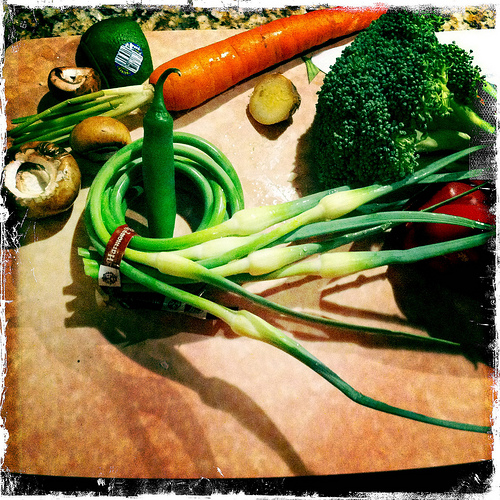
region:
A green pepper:
[141, 72, 201, 241]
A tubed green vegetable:
[79, 137, 489, 389]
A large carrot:
[155, 1, 402, 118]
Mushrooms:
[8, 117, 132, 248]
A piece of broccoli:
[306, 22, 498, 196]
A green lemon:
[71, 20, 163, 99]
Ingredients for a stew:
[14, 22, 499, 452]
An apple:
[372, 158, 499, 318]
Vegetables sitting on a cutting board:
[13, 28, 495, 465]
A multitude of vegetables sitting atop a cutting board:
[15, 21, 499, 453]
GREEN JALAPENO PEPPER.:
[113, 47, 193, 236]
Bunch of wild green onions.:
[128, 147, 455, 454]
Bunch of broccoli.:
[293, 23, 462, 208]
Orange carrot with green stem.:
[8, 0, 389, 116]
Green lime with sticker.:
[82, 19, 160, 104]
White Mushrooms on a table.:
[0, 110, 131, 225]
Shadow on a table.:
[36, 339, 361, 490]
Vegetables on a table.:
[0, 12, 481, 491]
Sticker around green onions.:
[68, 219, 148, 344]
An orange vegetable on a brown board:
[21, 26, 384, 104]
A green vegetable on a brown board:
[73, 218, 372, 383]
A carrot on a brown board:
[76, 17, 386, 84]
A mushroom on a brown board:
[16, 107, 100, 251]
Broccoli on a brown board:
[308, 44, 468, 215]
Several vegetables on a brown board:
[23, 57, 438, 311]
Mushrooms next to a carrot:
[20, 53, 137, 181]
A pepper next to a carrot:
[97, 49, 194, 207]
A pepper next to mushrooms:
[18, 123, 179, 231]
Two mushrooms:
[5, 130, 130, 227]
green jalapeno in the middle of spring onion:
[132, 47, 214, 251]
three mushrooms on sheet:
[10, 56, 124, 221]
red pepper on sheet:
[412, 177, 499, 260]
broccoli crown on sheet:
[305, 0, 498, 200]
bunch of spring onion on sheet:
[66, 111, 488, 436]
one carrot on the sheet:
[20, 0, 443, 155]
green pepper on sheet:
[61, 0, 167, 107]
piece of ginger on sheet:
[237, 58, 313, 154]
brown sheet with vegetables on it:
[10, 2, 499, 499]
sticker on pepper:
[112, 26, 157, 89]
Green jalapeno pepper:
[143, 66, 180, 238]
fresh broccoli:
[336, 17, 478, 167]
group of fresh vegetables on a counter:
[11, 16, 493, 396]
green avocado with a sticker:
[85, 22, 152, 82]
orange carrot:
[172, 14, 342, 69]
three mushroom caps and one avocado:
[11, 23, 143, 218]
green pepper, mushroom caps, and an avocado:
[17, 19, 199, 245]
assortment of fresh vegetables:
[16, 22, 482, 435]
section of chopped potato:
[249, 70, 309, 140]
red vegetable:
[416, 175, 494, 262]